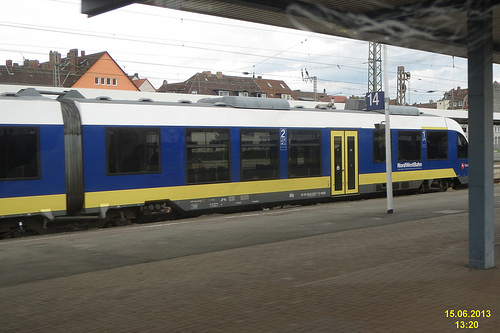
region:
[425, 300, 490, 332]
date that picture was taken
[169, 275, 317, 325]
part of the sidewalk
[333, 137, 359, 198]
door on the train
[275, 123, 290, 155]
number on the train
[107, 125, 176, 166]
window on the train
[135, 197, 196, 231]
part of train wheels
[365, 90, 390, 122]
number on the pole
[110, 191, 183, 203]
yellow area on train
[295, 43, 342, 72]
clouds in the sky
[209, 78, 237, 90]
roof on the house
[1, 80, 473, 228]
a blue, white and yellow train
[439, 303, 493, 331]
yellow time stamp in corner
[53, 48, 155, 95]
top of a pinkish orange house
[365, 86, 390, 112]
blue sign with white 14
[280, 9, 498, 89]
smoke streams in upper right corner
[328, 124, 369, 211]
two yellow doors on train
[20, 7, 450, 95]
several wires above train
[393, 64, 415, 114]
a metal tower beyond train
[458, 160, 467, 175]
a red sticker on front of train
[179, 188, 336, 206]
White writing on the lower gray part of train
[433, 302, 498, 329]
date picture was taken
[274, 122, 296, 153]
number on the bus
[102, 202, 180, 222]
part of train's wheel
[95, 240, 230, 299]
part of the sidewalk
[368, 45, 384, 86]
tower behind the train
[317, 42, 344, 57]
clouds in the sky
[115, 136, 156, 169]
window on the train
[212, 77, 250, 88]
roof on the house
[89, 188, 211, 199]
yellow color on train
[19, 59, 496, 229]
The train is at the train station.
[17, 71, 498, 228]
The train is not moving.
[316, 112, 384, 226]
the doors are yellow.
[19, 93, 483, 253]
The bus is blue and yellow.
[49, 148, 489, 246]
A yellow stripe is at the bottom of the bus.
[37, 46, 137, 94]
The roof is brown.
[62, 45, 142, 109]
the house is orange.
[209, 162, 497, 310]
The train station is clear.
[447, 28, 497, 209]
The pole is grey.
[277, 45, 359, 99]
The sky is cloudy.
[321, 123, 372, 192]
doors on the train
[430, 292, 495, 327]
date in bottom right corner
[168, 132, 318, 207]
windows on the train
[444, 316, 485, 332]
time in bottom right corner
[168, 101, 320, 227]
yellow, blue and white train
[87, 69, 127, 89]
windows on the building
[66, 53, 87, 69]
roof of the building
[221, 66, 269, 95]
roof of the building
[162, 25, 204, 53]
sky above the land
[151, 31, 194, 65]
wires above the land